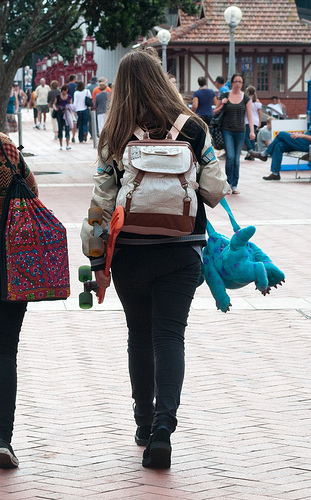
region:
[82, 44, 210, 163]
girl with long hair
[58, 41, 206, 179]
girl with brown hair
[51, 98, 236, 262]
girl wearing a backpack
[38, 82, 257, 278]
girl wearing a jacket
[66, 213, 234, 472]
girl wearing black pants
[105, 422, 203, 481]
girl wearing pair of black shoes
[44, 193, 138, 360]
girl carrying a skateboard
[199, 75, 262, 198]
woman wearing a brown tank top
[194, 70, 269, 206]
woman wearing bluejeans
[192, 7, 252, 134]
bubble electric street light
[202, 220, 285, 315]
a blue monster bag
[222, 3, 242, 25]
glass sphere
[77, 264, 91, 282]
a long board wheel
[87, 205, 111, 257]
longboard wheels and trucks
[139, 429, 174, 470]
the back of a woman's shoe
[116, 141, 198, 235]
a woman's brown and white backpack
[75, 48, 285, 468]
a woman carrying a longboard and bag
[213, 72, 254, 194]
a woman in a brown shirt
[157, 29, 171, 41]
glass bulb surrounding lightbulb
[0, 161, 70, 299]
pink patterned woman's bag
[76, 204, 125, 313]
a red and green skateboard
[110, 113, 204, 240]
a brown and beige backpack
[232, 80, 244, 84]
a woman's eyeglasses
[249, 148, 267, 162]
the shoe of a man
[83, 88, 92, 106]
a woman's black purse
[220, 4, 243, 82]
part of a lamp pole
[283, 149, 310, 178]
part of a bench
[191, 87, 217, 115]
a woman's short sleeve shirt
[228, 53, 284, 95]
a window of a building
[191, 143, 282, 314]
a blue stuffed animal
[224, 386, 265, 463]
the walkway is brick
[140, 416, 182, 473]
the shoe is black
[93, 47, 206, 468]
the girl is walking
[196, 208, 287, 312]
the girl is carrying a backpack shaped like a stuffed animal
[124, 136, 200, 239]
the girl is wearing a backpack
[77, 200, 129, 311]
the skateboard is orange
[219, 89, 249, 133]
the shirt is black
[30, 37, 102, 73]
the lampposts are red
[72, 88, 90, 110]
the shirt is white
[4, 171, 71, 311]
the backpack is multi-colored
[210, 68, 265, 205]
young women in glasses walking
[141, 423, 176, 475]
back side of black shoe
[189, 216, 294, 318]
blue animal backpack with purple polka dots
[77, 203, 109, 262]
two orange skateboard wheels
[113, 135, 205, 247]
tan backpack with brown straps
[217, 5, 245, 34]
glass globe on street lamp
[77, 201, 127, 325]
orange skateboard with green and orange wheels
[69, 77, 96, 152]
woman in white shirt holding black purse over shoulder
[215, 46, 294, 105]
4 windows with multiple panes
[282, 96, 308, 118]
multiple red bricks